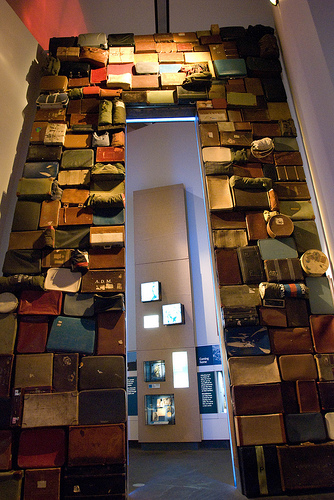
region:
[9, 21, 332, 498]
many wallets on display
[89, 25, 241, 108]
light on several wallets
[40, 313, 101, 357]
blue wallet between red ones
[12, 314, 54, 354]
red wallet next to blue wallet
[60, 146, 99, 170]
green wallet near a red wallet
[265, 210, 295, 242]
circle box near green wallets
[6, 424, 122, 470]
two red wallets together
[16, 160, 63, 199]
blue and green wallets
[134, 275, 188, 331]
two picture frames reflected on a mirror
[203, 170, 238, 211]
a white wallet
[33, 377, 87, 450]
a wall of pouches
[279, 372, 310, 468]
a wall of pouches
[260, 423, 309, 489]
a wall of pouches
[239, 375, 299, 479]
a wall of pouches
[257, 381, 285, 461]
a wall of pouches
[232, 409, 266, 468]
a wall of pouches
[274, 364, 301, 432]
a wall of pouches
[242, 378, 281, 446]
a wall of pouches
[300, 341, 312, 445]
a wall of pouches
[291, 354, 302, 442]
a wall of pouches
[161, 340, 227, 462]
white writing on the wall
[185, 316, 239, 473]
white writing on the wall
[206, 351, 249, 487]
white writing on the wall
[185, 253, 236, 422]
white writing on the wall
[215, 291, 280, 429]
big bricks are visible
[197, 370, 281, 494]
big bricks are visible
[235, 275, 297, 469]
big bricks are visible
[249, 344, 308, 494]
big bricks are visible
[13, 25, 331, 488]
a wall covered in suitcases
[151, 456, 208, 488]
brownish gray tile on the floor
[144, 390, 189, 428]
a lighted display on the wall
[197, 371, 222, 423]
a black informational sign on the wall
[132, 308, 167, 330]
a square light on the wall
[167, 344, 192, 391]
a rectangular light on the wall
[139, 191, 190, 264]
a beige wall inset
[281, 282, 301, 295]
blue and red stripes on a rolled bag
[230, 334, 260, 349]
white scratches on a blue suitcase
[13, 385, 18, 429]
white latches on brown suitcase